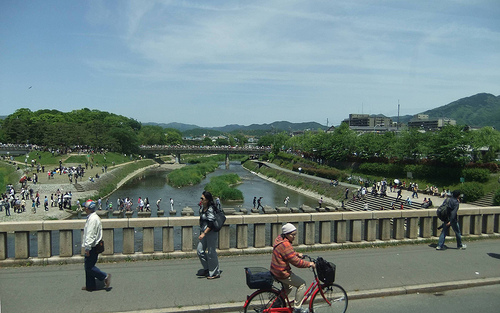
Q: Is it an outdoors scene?
A: Yes, it is outdoors.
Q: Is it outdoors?
A: Yes, it is outdoors.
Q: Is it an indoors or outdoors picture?
A: It is outdoors.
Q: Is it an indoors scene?
A: No, it is outdoors.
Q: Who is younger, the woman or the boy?
A: The boy is younger than the woman.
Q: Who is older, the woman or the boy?
A: The woman is older than the boy.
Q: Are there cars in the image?
A: No, there are no cars.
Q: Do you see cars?
A: No, there are no cars.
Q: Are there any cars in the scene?
A: No, there are no cars.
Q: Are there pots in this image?
A: No, there are no pots.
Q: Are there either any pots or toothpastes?
A: No, there are no pots or toothpastes.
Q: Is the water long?
A: Yes, the water is long.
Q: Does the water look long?
A: Yes, the water is long.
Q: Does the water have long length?
A: Yes, the water is long.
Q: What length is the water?
A: The water is long.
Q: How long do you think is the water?
A: The water is long.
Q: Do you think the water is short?
A: No, the water is long.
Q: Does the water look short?
A: No, the water is long.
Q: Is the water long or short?
A: The water is long.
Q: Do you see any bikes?
A: Yes, there is a bike.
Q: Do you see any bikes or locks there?
A: Yes, there is a bike.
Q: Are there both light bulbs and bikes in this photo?
A: No, there is a bike but no light bulbs.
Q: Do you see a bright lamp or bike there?
A: Yes, there is a bright bike.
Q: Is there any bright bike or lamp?
A: Yes, there is a bright bike.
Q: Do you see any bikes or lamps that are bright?
A: Yes, the bike is bright.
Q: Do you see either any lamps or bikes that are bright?
A: Yes, the bike is bright.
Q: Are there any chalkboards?
A: No, there are no chalkboards.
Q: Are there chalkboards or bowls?
A: No, there are no chalkboards or bowls.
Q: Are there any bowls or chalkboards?
A: No, there are no chalkboards or bowls.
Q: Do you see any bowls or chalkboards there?
A: No, there are no chalkboards or bowls.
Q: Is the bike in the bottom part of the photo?
A: Yes, the bike is in the bottom of the image.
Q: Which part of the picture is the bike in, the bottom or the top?
A: The bike is in the bottom of the image.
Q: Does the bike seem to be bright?
A: Yes, the bike is bright.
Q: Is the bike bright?
A: Yes, the bike is bright.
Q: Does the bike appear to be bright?
A: Yes, the bike is bright.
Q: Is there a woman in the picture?
A: Yes, there is a woman.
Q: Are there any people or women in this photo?
A: Yes, there is a woman.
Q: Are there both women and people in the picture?
A: Yes, there are both a woman and people.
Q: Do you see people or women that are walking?
A: Yes, the woman is walking.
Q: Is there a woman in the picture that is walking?
A: Yes, there is a woman that is walking.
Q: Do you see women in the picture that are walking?
A: Yes, there is a woman that is walking.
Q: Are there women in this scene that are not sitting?
A: Yes, there is a woman that is walking.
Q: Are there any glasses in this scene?
A: No, there are no glasses.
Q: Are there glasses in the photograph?
A: No, there are no glasses.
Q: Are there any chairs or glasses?
A: No, there are no glasses or chairs.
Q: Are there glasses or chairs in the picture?
A: No, there are no glasses or chairs.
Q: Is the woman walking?
A: Yes, the woman is walking.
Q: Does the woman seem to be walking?
A: Yes, the woman is walking.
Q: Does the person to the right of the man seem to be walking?
A: Yes, the woman is walking.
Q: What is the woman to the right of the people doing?
A: The woman is walking.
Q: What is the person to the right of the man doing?
A: The woman is walking.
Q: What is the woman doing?
A: The woman is walking.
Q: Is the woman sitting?
A: No, the woman is walking.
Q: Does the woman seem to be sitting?
A: No, the woman is walking.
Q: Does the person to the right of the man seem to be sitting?
A: No, the woman is walking.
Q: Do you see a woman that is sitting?
A: No, there is a woman but she is walking.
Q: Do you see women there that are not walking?
A: No, there is a woman but she is walking.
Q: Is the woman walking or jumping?
A: The woman is walking.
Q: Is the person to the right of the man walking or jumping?
A: The woman is walking.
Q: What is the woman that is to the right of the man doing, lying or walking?
A: The woman is walking.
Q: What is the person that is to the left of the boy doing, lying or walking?
A: The woman is walking.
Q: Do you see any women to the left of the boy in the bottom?
A: Yes, there is a woman to the left of the boy.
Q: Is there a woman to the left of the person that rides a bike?
A: Yes, there is a woman to the left of the boy.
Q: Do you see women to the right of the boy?
A: No, the woman is to the left of the boy.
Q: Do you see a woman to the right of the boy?
A: No, the woman is to the left of the boy.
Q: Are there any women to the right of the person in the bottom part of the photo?
A: No, the woman is to the left of the boy.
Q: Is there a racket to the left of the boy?
A: No, there is a woman to the left of the boy.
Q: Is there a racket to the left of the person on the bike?
A: No, there is a woman to the left of the boy.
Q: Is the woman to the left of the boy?
A: Yes, the woman is to the left of the boy.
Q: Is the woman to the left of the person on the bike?
A: Yes, the woman is to the left of the boy.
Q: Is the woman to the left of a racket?
A: No, the woman is to the left of the boy.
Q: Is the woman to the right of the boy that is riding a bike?
A: No, the woman is to the left of the boy.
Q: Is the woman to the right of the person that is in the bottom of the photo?
A: No, the woman is to the left of the boy.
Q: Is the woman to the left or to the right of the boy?
A: The woman is to the left of the boy.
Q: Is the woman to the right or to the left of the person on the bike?
A: The woman is to the left of the boy.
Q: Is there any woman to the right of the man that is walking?
A: Yes, there is a woman to the right of the man.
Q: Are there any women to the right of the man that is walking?
A: Yes, there is a woman to the right of the man.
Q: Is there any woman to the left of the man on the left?
A: No, the woman is to the right of the man.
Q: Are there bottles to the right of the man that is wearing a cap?
A: No, there is a woman to the right of the man.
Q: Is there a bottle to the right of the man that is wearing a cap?
A: No, there is a woman to the right of the man.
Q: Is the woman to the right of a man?
A: Yes, the woman is to the right of a man.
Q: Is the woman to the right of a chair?
A: No, the woman is to the right of a man.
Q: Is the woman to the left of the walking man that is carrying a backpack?
A: No, the woman is to the right of the man.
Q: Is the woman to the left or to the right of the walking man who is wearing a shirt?
A: The woman is to the right of the man.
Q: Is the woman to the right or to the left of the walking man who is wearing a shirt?
A: The woman is to the right of the man.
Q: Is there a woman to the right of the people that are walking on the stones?
A: Yes, there is a woman to the right of the people.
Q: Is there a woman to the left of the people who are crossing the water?
A: No, the woman is to the right of the people.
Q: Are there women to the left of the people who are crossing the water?
A: No, the woman is to the right of the people.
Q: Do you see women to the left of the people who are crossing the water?
A: No, the woman is to the right of the people.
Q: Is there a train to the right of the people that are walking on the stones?
A: No, there is a woman to the right of the people.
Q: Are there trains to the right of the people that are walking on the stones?
A: No, there is a woman to the right of the people.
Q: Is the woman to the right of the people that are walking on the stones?
A: Yes, the woman is to the right of the people.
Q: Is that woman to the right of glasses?
A: No, the woman is to the right of the people.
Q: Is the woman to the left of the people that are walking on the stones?
A: No, the woman is to the right of the people.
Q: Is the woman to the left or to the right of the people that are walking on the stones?
A: The woman is to the right of the people.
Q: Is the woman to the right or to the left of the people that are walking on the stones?
A: The woman is to the right of the people.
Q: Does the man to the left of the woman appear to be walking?
A: Yes, the man is walking.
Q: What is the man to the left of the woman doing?
A: The man is walking.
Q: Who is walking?
A: The man is walking.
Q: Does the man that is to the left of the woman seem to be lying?
A: No, the man is walking.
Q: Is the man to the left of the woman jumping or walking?
A: The man is walking.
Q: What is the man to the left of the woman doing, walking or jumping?
A: The man is walking.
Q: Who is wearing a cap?
A: The man is wearing a cap.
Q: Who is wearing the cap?
A: The man is wearing a cap.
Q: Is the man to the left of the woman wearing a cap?
A: Yes, the man is wearing a cap.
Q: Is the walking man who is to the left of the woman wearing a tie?
A: No, the man is wearing a cap.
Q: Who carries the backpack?
A: The man carries the backpack.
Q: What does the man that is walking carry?
A: The man carries a backpack.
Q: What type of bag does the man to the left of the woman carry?
A: The man carries a backpack.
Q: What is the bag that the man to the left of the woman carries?
A: The bag is a backpack.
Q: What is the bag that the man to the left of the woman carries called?
A: The bag is a backpack.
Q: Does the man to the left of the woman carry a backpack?
A: Yes, the man carries a backpack.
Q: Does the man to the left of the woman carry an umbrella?
A: No, the man carries a backpack.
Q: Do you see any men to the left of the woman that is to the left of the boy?
A: Yes, there is a man to the left of the woman.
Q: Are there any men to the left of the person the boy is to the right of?
A: Yes, there is a man to the left of the woman.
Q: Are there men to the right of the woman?
A: No, the man is to the left of the woman.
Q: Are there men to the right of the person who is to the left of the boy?
A: No, the man is to the left of the woman.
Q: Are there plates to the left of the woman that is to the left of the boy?
A: No, there is a man to the left of the woman.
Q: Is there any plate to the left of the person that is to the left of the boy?
A: No, there is a man to the left of the woman.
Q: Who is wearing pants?
A: The man is wearing pants.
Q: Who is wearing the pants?
A: The man is wearing pants.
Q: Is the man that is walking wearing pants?
A: Yes, the man is wearing pants.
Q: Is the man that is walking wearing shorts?
A: No, the man is wearing pants.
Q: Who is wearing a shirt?
A: The man is wearing a shirt.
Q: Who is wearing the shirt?
A: The man is wearing a shirt.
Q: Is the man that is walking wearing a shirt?
A: Yes, the man is wearing a shirt.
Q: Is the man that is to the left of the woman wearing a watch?
A: No, the man is wearing a shirt.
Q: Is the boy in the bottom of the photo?
A: Yes, the boy is in the bottom of the image.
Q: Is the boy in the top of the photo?
A: No, the boy is in the bottom of the image.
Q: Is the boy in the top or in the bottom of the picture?
A: The boy is in the bottom of the image.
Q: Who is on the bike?
A: The boy is on the bike.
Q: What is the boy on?
A: The boy is on the bike.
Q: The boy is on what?
A: The boy is on the bike.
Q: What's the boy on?
A: The boy is on the bike.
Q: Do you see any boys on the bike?
A: Yes, there is a boy on the bike.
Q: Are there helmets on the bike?
A: No, there is a boy on the bike.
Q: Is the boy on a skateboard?
A: No, the boy is on the bike.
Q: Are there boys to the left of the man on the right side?
A: Yes, there is a boy to the left of the man.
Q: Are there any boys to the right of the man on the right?
A: No, the boy is to the left of the man.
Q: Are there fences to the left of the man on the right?
A: No, there is a boy to the left of the man.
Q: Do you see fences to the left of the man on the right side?
A: No, there is a boy to the left of the man.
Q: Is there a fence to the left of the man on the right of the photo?
A: No, there is a boy to the left of the man.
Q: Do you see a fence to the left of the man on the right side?
A: No, there is a boy to the left of the man.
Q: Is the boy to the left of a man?
A: Yes, the boy is to the left of a man.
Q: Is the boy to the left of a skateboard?
A: No, the boy is to the left of a man.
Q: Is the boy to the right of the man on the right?
A: No, the boy is to the left of the man.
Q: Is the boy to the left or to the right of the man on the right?
A: The boy is to the left of the man.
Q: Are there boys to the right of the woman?
A: Yes, there is a boy to the right of the woman.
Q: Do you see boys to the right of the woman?
A: Yes, there is a boy to the right of the woman.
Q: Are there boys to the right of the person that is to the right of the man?
A: Yes, there is a boy to the right of the woman.